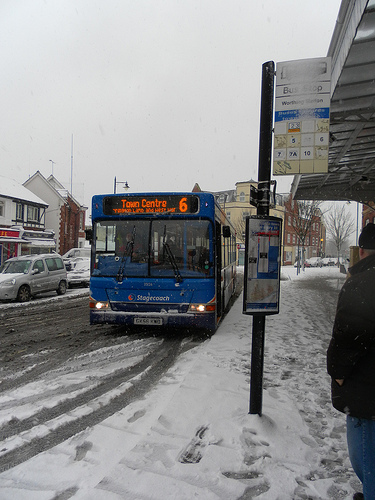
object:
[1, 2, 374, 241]
sky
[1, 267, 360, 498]
snow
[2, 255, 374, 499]
ground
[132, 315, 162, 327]
license plate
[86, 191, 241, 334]
bus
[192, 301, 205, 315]
headlights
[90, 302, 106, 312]
headlights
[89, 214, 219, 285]
windshield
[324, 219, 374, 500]
person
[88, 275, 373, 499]
sidewalk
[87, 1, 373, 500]
stop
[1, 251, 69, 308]
vehicles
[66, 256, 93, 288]
vehicles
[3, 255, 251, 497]
road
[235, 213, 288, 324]
sign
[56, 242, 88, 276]
suv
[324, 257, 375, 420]
jacket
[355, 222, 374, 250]
hat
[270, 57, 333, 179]
sign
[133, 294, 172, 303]
logo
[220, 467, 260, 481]
footprint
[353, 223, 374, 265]
head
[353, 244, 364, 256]
ear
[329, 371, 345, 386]
hand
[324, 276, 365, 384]
arm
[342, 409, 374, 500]
pants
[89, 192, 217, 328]
front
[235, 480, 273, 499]
footprint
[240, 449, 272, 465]
footprint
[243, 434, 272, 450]
footprint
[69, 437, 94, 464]
footprint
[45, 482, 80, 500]
footprint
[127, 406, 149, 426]
footprint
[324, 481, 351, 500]
footprint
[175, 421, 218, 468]
tracks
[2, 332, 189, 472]
tracks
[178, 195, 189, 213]
number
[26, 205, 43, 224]
windows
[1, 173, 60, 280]
building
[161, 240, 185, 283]
wipers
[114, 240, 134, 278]
wipers